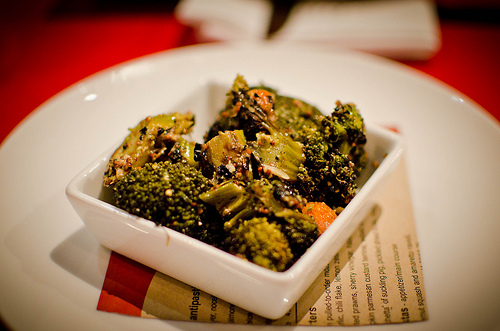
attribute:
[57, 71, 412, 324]
bowl — white, square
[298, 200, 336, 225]
small carrot — round, cooked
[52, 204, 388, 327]
bowl shadow — ON THE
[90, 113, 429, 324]
paper — UNDER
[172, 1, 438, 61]
towel — White 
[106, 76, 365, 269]
broccoli — green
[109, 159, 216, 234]
floret — green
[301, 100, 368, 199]
floret — green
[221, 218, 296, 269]
floret — green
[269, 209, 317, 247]
floret — green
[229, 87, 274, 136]
floret — green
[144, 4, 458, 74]
white towel — IS ON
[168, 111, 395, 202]
floret — green, broccoli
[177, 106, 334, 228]
broccoli — cooked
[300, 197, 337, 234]
carrot — sliced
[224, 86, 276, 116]
carrot — sliced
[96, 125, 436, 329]
paper — square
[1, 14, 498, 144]
table — red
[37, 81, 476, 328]
plate — white, red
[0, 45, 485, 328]
plate — UNDER, round, white